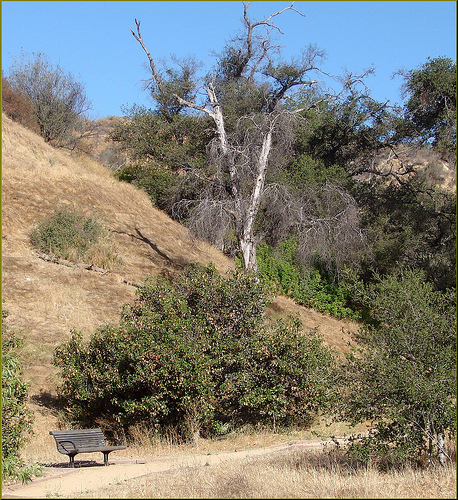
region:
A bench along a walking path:
[47, 426, 126, 466]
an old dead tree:
[134, 5, 313, 306]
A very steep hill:
[5, 111, 349, 414]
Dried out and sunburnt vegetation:
[170, 462, 447, 496]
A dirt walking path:
[11, 424, 383, 493]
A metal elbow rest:
[57, 438, 81, 451]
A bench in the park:
[48, 421, 125, 460]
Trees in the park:
[134, 299, 284, 416]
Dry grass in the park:
[306, 459, 374, 498]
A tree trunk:
[234, 171, 271, 281]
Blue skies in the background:
[72, 25, 109, 85]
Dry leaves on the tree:
[283, 181, 347, 252]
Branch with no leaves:
[129, 20, 174, 99]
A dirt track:
[231, 428, 291, 460]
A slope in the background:
[32, 144, 122, 231]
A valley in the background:
[81, 122, 164, 195]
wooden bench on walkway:
[40, 422, 131, 469]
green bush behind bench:
[53, 254, 337, 446]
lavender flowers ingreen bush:
[203, 303, 240, 333]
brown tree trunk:
[232, 226, 260, 275]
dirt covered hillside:
[2, 105, 365, 449]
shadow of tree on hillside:
[104, 208, 175, 272]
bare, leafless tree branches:
[167, 184, 235, 243]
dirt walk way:
[0, 434, 353, 498]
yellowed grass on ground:
[97, 454, 456, 498]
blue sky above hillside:
[2, 2, 457, 153]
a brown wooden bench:
[27, 335, 207, 499]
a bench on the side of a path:
[30, 375, 364, 478]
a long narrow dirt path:
[44, 358, 413, 481]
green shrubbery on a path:
[93, 236, 369, 474]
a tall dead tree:
[139, 63, 342, 356]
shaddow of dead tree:
[117, 217, 285, 317]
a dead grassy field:
[214, 433, 425, 497]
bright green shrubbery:
[251, 226, 395, 328]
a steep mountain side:
[4, 59, 371, 413]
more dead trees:
[107, 11, 326, 134]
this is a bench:
[44, 405, 127, 473]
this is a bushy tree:
[61, 256, 325, 428]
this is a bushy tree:
[29, 204, 125, 272]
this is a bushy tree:
[352, 279, 454, 468]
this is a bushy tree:
[112, 85, 351, 262]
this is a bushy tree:
[330, 138, 454, 277]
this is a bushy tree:
[400, 58, 454, 163]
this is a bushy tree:
[8, 54, 93, 150]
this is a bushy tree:
[250, 232, 363, 330]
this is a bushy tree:
[70, 318, 255, 454]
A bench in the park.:
[50, 413, 127, 470]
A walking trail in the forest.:
[89, 426, 319, 486]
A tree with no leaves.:
[197, 58, 300, 256]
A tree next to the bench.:
[93, 321, 245, 439]